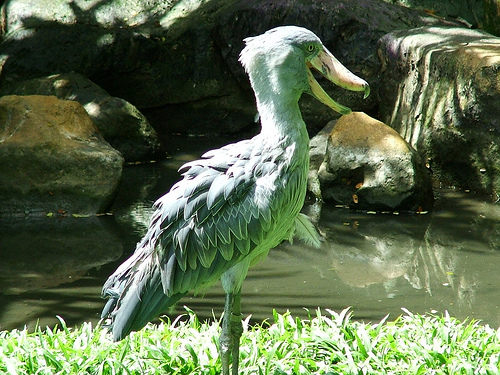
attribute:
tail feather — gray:
[106, 255, 170, 342]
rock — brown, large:
[0, 90, 128, 228]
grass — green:
[0, 313, 497, 373]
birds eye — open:
[297, 31, 324, 61]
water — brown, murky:
[340, 254, 430, 304]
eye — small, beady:
[98, 19, 375, 374]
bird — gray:
[148, 6, 390, 301]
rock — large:
[7, 85, 125, 222]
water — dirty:
[3, 199, 498, 319]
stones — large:
[2, 89, 127, 219]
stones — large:
[299, 105, 416, 216]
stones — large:
[369, 18, 498, 209]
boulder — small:
[279, 97, 434, 224]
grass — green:
[2, 302, 498, 373]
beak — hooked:
[307, 46, 369, 116]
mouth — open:
[302, 57, 372, 117]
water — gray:
[385, 253, 437, 295]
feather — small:
[296, 212, 326, 253]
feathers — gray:
[205, 172, 227, 209]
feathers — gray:
[183, 189, 206, 221]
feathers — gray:
[175, 160, 206, 172]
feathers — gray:
[243, 156, 255, 183]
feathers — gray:
[177, 228, 189, 256]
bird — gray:
[84, 27, 387, 372]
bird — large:
[94, 21, 369, 368]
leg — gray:
[231, 290, 245, 372]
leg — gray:
[215, 296, 230, 373]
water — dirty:
[304, 251, 499, 310]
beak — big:
[306, 43, 371, 113]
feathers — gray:
[189, 144, 262, 266]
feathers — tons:
[192, 168, 300, 274]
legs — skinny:
[213, 268, 245, 373]